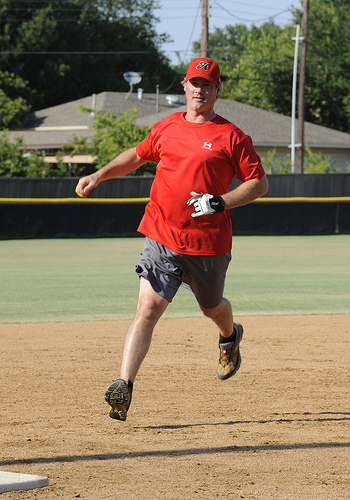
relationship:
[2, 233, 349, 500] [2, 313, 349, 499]
ground has dirt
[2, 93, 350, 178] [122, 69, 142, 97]
house has antenna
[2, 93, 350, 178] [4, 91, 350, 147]
house has roof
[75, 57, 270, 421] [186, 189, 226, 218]
man has glove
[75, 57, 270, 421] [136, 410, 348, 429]
man has shadow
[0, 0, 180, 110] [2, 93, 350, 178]
tree behind house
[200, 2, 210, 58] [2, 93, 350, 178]
pole behind house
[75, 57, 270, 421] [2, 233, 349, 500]
man on top of ground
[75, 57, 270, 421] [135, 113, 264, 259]
man has shirt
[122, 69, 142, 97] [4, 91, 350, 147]
antenna on top of roof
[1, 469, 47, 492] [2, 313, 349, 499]
baseball base on top of dirt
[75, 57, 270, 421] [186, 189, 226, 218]
man wearing glove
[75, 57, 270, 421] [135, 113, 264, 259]
man wearing shirt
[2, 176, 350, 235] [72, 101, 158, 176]
fence against tree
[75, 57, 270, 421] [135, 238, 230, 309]
man wearing shorts